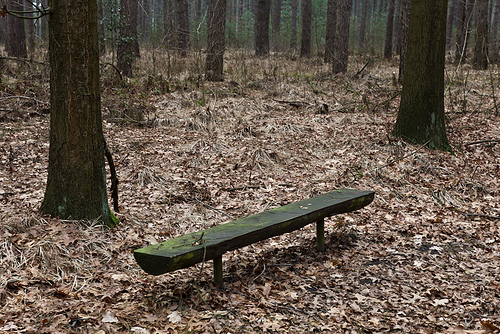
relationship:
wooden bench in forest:
[133, 186, 374, 303] [0, 2, 499, 332]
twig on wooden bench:
[194, 225, 211, 285] [130, 186, 378, 287]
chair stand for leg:
[210, 252, 225, 289] [313, 214, 327, 250]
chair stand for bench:
[210, 252, 225, 289] [134, 185, 376, 285]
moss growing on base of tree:
[424, 111, 456, 153] [392, 1, 452, 152]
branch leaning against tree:
[103, 144, 123, 213] [40, 2, 115, 222]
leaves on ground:
[352, 219, 433, 286] [258, 114, 320, 173]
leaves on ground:
[166, 149, 314, 196] [209, 136, 291, 191]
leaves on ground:
[157, 122, 292, 203] [185, 111, 269, 191]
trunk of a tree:
[401, 78, 442, 143] [47, 0, 109, 220]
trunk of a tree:
[332, 52, 347, 72] [405, 3, 445, 147]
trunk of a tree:
[204, 47, 223, 81] [337, 3, 345, 71]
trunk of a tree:
[52, 127, 103, 219] [207, 2, 222, 83]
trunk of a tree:
[401, 78, 442, 143] [256, 0, 268, 59]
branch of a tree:
[2, 3, 49, 22] [40, 2, 115, 222]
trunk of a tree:
[389, 0, 454, 158] [392, 1, 452, 152]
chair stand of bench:
[210, 252, 225, 289] [134, 185, 376, 285]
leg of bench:
[314, 214, 327, 249] [134, 185, 376, 285]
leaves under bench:
[185, 229, 340, 262] [109, 179, 376, 286]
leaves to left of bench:
[47, 252, 93, 288] [134, 185, 376, 285]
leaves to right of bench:
[355, 164, 455, 254] [134, 185, 376, 285]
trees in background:
[0, 0, 500, 227] [2, 1, 497, 162]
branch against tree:
[69, 124, 127, 225] [40, 2, 115, 222]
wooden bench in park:
[130, 186, 378, 287] [1, 1, 497, 331]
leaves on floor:
[6, 96, 498, 331] [266, 253, 371, 331]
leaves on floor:
[400, 186, 487, 286] [0, 46, 498, 333]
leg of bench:
[313, 214, 327, 250] [130, 182, 372, 297]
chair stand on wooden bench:
[210, 252, 225, 289] [130, 186, 378, 287]